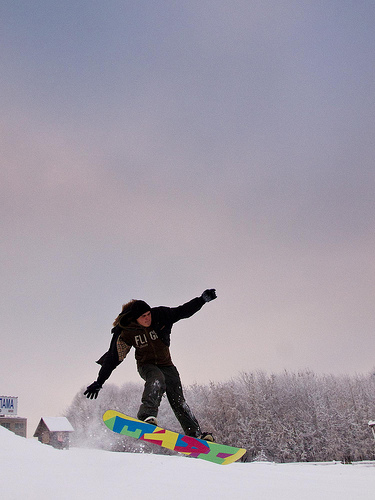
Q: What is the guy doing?
A: Snowboarding.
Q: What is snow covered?
A: Trees.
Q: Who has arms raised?
A: Snowboarder.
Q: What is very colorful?
A: Snowboard.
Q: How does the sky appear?
A: Overcast.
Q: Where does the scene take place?
A: On a ski slope.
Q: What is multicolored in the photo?
A: The snowboard.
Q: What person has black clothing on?
A: The snowboarder.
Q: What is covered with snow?
A: The pine trees.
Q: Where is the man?
A: On the snowboard.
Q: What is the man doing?
A: Snowboarding.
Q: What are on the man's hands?
A: Gloves.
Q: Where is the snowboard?
A: Under the man.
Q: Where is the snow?
A: On the ground.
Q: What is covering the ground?
A: Snow.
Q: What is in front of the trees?
A: Buildings.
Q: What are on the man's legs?
A: Jeans.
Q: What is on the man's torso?
A: A coat.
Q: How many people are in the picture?
A: One.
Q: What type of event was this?
A: Snowboarding contest.